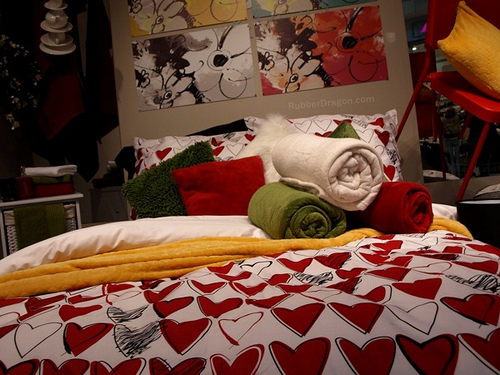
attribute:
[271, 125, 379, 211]
blanket — rolled up, white, off white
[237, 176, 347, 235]
blanket — rolled up, green, olive green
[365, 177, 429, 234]
blanket — rolled up, red, dark red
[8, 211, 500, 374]
blanket — white, red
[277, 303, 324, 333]
heart — red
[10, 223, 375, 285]
blanket — yellow, gold, folded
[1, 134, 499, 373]
bed — made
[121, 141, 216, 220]
pillow — green, dark green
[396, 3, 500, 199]
chair — red, metal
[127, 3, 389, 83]
picture — black, white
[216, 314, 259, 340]
heart — black, white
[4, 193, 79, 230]
table — white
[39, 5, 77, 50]
light fixture — white